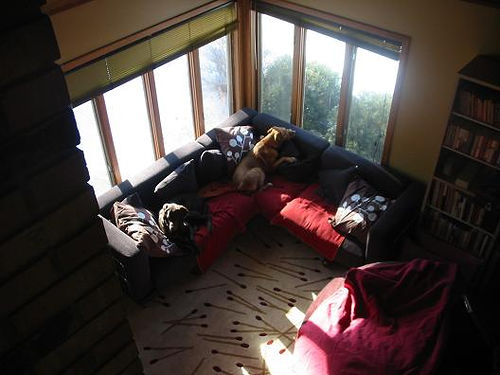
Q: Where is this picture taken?
A: A living room.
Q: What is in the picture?
A: A sofa.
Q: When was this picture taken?
A: Daytime.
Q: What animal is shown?
A: A dog.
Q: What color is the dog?
A: Gold.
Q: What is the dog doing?
A: Looking out the window.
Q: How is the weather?
A: Sunny.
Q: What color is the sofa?
A: Red.